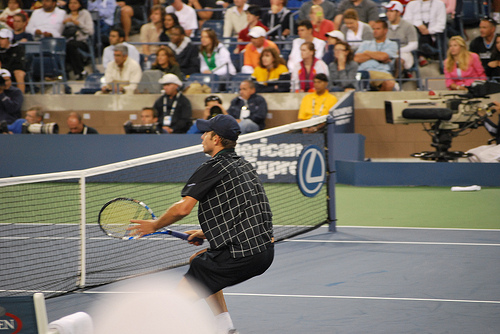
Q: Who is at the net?
A: The tennis player.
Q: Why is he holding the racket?
A: To hit the ball.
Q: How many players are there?
A: One.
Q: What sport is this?
A: Tennis.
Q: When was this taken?
A: During a game.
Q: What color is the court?
A: Blue.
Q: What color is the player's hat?
A: Black.